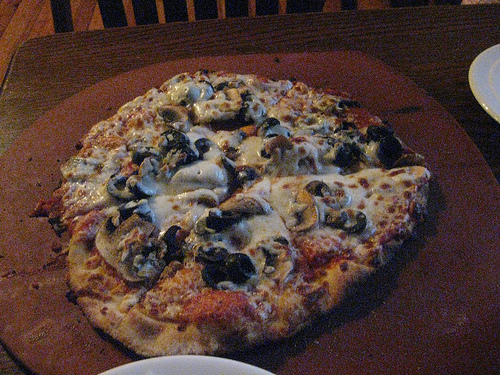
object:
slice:
[258, 164, 438, 316]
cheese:
[146, 154, 220, 226]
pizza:
[19, 47, 457, 375]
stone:
[332, 34, 462, 165]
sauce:
[297, 227, 348, 271]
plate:
[463, 37, 498, 139]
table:
[436, 135, 483, 195]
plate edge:
[99, 356, 274, 373]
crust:
[64, 263, 147, 341]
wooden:
[55, 2, 291, 17]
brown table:
[7, 14, 486, 61]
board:
[0, 21, 480, 359]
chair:
[24, 0, 482, 44]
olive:
[329, 138, 373, 171]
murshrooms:
[219, 195, 262, 217]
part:
[470, 62, 484, 79]